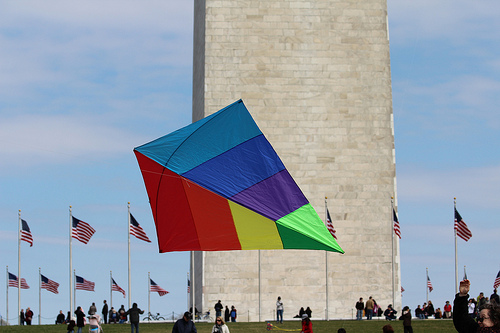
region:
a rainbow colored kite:
[120, 90, 360, 278]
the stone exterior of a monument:
[204, 10, 391, 132]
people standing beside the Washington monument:
[2, 3, 490, 324]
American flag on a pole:
[441, 196, 478, 265]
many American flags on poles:
[0, 186, 491, 309]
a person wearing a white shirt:
[269, 293, 285, 308]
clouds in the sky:
[25, 82, 114, 159]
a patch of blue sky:
[426, 142, 493, 162]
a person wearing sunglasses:
[215, 317, 226, 327]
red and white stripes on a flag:
[79, 226, 95, 241]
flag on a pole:
[437, 198, 468, 244]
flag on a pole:
[380, 186, 406, 248]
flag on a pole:
[140, 268, 170, 309]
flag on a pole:
[121, 198, 146, 254]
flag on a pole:
[98, 270, 123, 296]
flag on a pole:
[68, 260, 98, 292]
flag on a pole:
[53, 195, 91, 250]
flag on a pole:
[30, 265, 67, 298]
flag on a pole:
[5, 205, 46, 241]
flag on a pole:
[10, 263, 30, 295]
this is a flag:
[48, 74, 398, 314]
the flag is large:
[157, 169, 286, 273]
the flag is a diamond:
[101, 51, 380, 321]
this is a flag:
[62, 166, 94, 243]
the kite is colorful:
[120, 131, 377, 305]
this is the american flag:
[56, 205, 113, 257]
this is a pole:
[51, 260, 104, 280]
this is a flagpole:
[23, 246, 114, 275]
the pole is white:
[11, 244, 143, 330]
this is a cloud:
[39, 147, 115, 203]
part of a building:
[378, 83, 390, 96]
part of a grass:
[346, 318, 354, 324]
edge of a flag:
[176, 291, 181, 299]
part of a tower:
[378, 175, 398, 199]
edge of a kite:
[287, 227, 296, 238]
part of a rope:
[153, 231, 168, 238]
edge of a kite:
[244, 113, 251, 130]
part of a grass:
[331, 319, 334, 321]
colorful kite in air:
[125, 110, 328, 271]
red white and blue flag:
[52, 201, 98, 255]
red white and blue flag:
[110, 202, 155, 249]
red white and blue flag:
[430, 196, 480, 260]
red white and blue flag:
[0, 206, 35, 246]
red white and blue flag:
[137, 270, 158, 293]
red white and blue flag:
[106, 272, 138, 299]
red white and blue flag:
[66, 273, 92, 293]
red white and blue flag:
[17, 270, 64, 298]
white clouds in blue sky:
[68, 53, 110, 106]